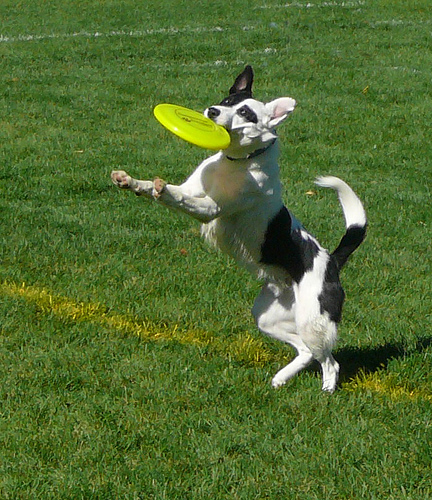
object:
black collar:
[222, 129, 276, 163]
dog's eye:
[237, 107, 249, 117]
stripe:
[0, 261, 431, 407]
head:
[201, 65, 302, 149]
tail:
[309, 173, 369, 270]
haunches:
[310, 250, 348, 358]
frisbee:
[152, 102, 231, 147]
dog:
[111, 65, 368, 395]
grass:
[1, 0, 432, 499]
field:
[2, 2, 431, 499]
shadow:
[301, 334, 432, 386]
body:
[109, 141, 369, 395]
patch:
[234, 102, 259, 126]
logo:
[179, 114, 193, 124]